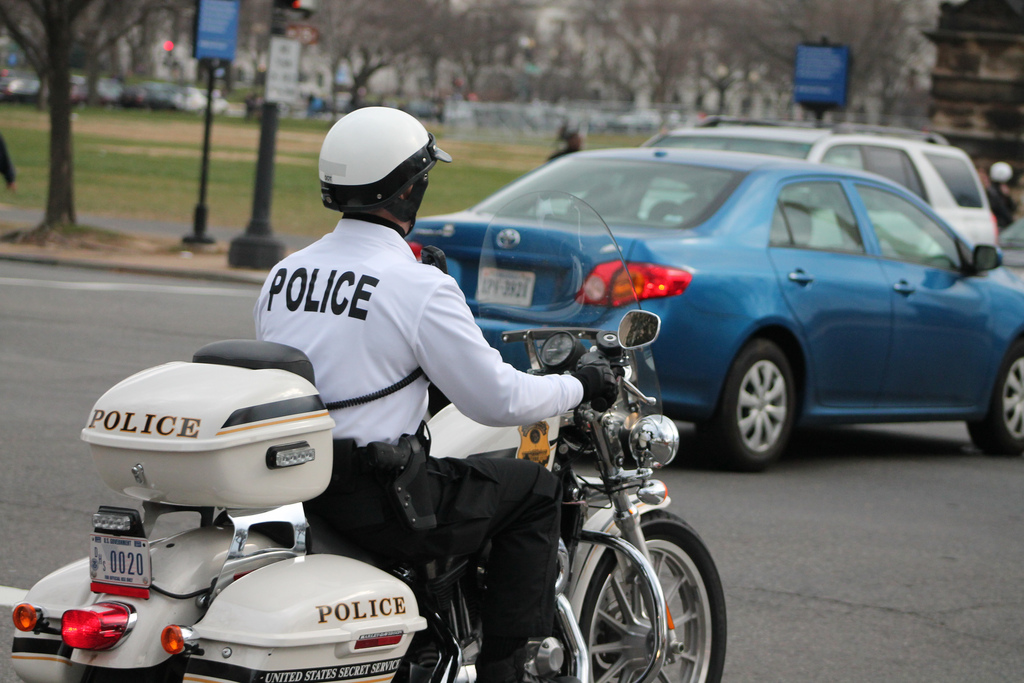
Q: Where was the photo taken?
A: On the street.